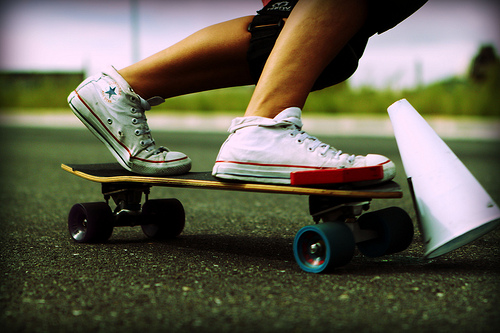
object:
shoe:
[67, 65, 192, 175]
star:
[105, 86, 117, 99]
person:
[67, 0, 428, 185]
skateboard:
[61, 162, 414, 273]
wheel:
[293, 222, 355, 273]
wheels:
[68, 202, 113, 243]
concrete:
[2, 125, 499, 329]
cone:
[387, 98, 500, 260]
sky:
[4, 2, 500, 89]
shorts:
[354, 0, 430, 34]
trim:
[61, 163, 403, 199]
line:
[74, 89, 188, 163]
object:
[290, 166, 384, 186]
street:
[0, 128, 496, 329]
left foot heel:
[66, 75, 108, 123]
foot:
[211, 127, 397, 185]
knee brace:
[246, 0, 369, 92]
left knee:
[306, 0, 370, 92]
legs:
[155, 15, 255, 97]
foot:
[67, 65, 192, 176]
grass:
[0, 77, 499, 122]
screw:
[310, 244, 318, 254]